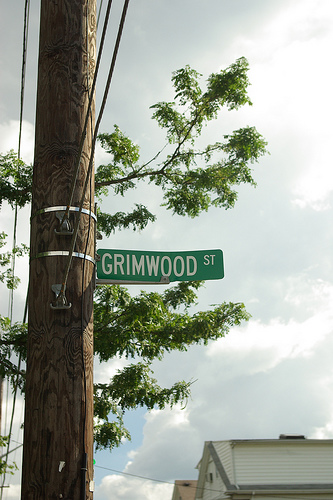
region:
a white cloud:
[272, 69, 319, 117]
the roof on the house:
[251, 453, 297, 474]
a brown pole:
[42, 377, 87, 452]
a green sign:
[103, 251, 222, 277]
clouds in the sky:
[289, 179, 322, 205]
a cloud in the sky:
[250, 331, 306, 362]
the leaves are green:
[125, 374, 164, 402]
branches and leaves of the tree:
[103, 302, 214, 346]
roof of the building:
[223, 442, 330, 478]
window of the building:
[204, 466, 218, 486]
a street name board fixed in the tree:
[93, 245, 222, 282]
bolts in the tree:
[96, 250, 101, 275]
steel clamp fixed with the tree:
[24, 203, 111, 271]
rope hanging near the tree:
[66, 34, 106, 199]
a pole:
[34, 367, 94, 499]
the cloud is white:
[138, 425, 186, 461]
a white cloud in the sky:
[140, 438, 174, 468]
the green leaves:
[200, 306, 243, 329]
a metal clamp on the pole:
[55, 248, 70, 257]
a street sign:
[100, 251, 220, 278]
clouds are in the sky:
[137, 446, 199, 475]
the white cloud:
[246, 328, 308, 356]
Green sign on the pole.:
[95, 239, 226, 289]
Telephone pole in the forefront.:
[14, 0, 98, 499]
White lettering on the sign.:
[94, 247, 218, 280]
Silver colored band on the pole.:
[27, 246, 97, 265]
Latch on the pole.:
[44, 280, 76, 314]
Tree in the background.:
[0, 46, 263, 490]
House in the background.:
[189, 427, 332, 499]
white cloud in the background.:
[97, 310, 331, 499]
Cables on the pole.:
[53, 0, 141, 311]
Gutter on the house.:
[228, 443, 242, 495]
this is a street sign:
[94, 225, 227, 320]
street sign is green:
[96, 235, 232, 301]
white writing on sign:
[86, 227, 241, 313]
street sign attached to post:
[11, 149, 235, 493]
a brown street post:
[16, 18, 112, 478]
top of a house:
[183, 430, 314, 499]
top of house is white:
[187, 429, 323, 499]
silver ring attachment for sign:
[29, 201, 121, 286]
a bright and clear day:
[21, 206, 316, 495]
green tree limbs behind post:
[13, 242, 210, 435]